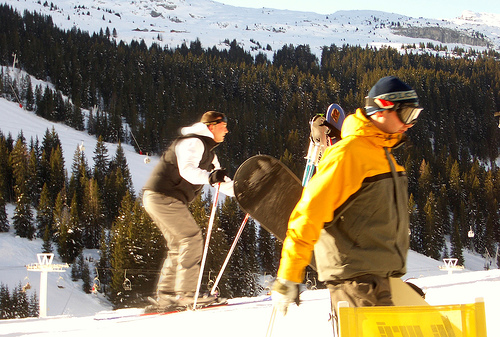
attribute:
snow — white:
[66, 135, 86, 150]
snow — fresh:
[418, 258, 434, 274]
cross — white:
[437, 255, 464, 277]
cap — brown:
[376, 75, 420, 93]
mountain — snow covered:
[139, 24, 383, 49]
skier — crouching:
[133, 106, 243, 309]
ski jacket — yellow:
[319, 152, 399, 204]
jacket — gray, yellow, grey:
[346, 203, 400, 268]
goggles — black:
[402, 108, 422, 122]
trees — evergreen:
[304, 58, 339, 77]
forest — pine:
[62, 47, 123, 85]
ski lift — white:
[7, 62, 32, 101]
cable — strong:
[463, 223, 482, 240]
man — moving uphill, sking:
[176, 109, 239, 156]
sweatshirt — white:
[177, 142, 199, 171]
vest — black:
[162, 171, 180, 186]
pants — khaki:
[144, 206, 203, 273]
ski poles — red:
[211, 190, 223, 210]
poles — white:
[198, 211, 215, 265]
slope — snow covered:
[57, 131, 100, 154]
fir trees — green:
[357, 56, 408, 65]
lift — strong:
[122, 282, 139, 290]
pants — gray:
[336, 286, 385, 308]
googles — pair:
[396, 106, 406, 116]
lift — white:
[466, 226, 476, 241]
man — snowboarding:
[337, 74, 425, 310]